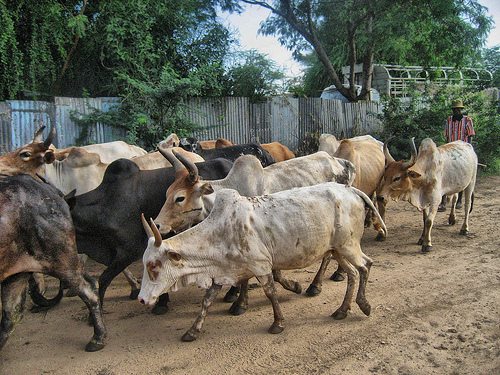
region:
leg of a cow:
[338, 233, 377, 323]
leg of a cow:
[330, 249, 357, 323]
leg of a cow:
[253, 268, 285, 335]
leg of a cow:
[178, 278, 220, 345]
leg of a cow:
[58, 266, 107, 351]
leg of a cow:
[93, 249, 124, 318]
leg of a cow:
[311, 253, 328, 283]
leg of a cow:
[421, 205, 438, 242]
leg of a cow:
[462, 183, 474, 227]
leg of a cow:
[450, 190, 457, 221]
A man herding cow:
[312, 86, 499, 286]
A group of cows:
[17, 126, 399, 338]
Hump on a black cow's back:
[96, 153, 141, 193]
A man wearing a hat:
[436, 86, 479, 133]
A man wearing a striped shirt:
[435, 85, 471, 141]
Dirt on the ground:
[402, 261, 483, 371]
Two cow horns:
[148, 141, 200, 183]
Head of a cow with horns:
[128, 212, 180, 313]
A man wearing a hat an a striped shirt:
[440, 89, 479, 149]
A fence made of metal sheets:
[255, 95, 374, 126]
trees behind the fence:
[2, 2, 254, 92]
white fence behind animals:
[10, 101, 121, 139]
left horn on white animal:
[150, 219, 165, 243]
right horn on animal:
[138, 214, 154, 236]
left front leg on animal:
[259, 274, 289, 325]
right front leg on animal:
[186, 272, 217, 356]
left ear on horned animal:
[410, 164, 426, 186]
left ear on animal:
[165, 250, 185, 265]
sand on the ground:
[300, 337, 335, 368]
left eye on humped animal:
[173, 187, 185, 202]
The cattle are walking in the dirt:
[11, 88, 431, 360]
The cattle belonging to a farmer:
[13, 93, 426, 345]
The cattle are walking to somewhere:
[10, 107, 431, 355]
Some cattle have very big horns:
[13, 130, 434, 341]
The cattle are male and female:
[16, 125, 426, 357]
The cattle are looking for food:
[5, 135, 423, 352]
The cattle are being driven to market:
[20, 110, 426, 356]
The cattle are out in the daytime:
[40, 105, 411, 371]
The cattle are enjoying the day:
[25, 121, 408, 353]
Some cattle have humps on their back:
[10, 127, 427, 358]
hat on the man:
[452, 100, 465, 106]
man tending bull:
[446, 97, 473, 137]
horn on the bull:
[397, 135, 424, 165]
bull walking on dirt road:
[376, 132, 483, 246]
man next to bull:
[431, 100, 481, 138]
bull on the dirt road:
[133, 181, 388, 337]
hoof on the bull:
[84, 336, 112, 357]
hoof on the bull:
[178, 324, 203, 342]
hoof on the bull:
[264, 318, 286, 333]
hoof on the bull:
[327, 302, 350, 323]